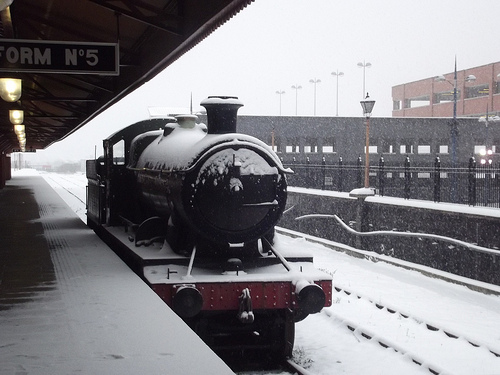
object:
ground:
[0, 293, 231, 375]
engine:
[125, 94, 294, 258]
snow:
[399, 281, 500, 328]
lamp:
[360, 92, 376, 116]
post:
[364, 119, 369, 189]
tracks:
[301, 326, 434, 375]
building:
[390, 60, 500, 116]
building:
[234, 114, 500, 203]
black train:
[84, 96, 332, 358]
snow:
[150, 138, 202, 159]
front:
[149, 280, 333, 311]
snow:
[303, 342, 405, 375]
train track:
[414, 279, 500, 354]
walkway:
[0, 165, 233, 375]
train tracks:
[235, 358, 308, 375]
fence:
[285, 189, 500, 286]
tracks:
[407, 343, 500, 375]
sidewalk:
[2, 177, 92, 272]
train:
[85, 92, 331, 359]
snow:
[329, 260, 427, 300]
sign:
[0, 34, 120, 75]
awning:
[0, 0, 253, 149]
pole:
[364, 117, 369, 188]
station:
[1, 0, 253, 375]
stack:
[200, 95, 244, 134]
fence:
[277, 155, 498, 206]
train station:
[0, 0, 253, 375]